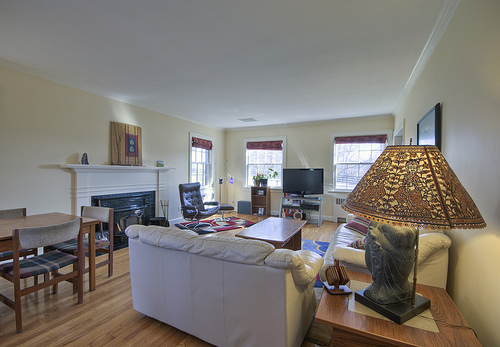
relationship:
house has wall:
[1, 1, 498, 341] [7, 84, 227, 207]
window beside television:
[246, 140, 285, 186] [282, 166, 322, 201]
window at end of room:
[245, 162, 286, 189] [9, 12, 494, 337]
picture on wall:
[106, 121, 153, 169] [45, 98, 110, 158]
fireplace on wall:
[56, 149, 193, 254] [0, 57, 465, 210]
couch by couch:
[118, 217, 318, 345] [318, 209, 447, 291]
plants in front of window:
[249, 166, 280, 186] [243, 139, 287, 190]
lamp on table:
[307, 160, 457, 335] [294, 263, 418, 340]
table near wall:
[294, 263, 418, 340] [395, 0, 497, 343]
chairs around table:
[31, 213, 143, 303] [15, 206, 102, 247]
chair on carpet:
[175, 180, 224, 220] [193, 202, 270, 243]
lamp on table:
[339, 144, 489, 326] [305, 259, 488, 345]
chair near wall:
[178, 182, 221, 232] [6, 75, 221, 270]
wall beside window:
[6, 75, 221, 270] [190, 133, 214, 208]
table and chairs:
[0, 211, 73, 250] [0, 216, 87, 333]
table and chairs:
[0, 211, 73, 250] [77, 204, 116, 282]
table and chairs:
[0, 211, 73, 250] [176, 180, 220, 228]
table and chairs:
[0, 211, 73, 250] [0, 206, 27, 219]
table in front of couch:
[0, 211, 99, 293] [127, 228, 308, 345]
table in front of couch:
[246, 211, 297, 243] [127, 228, 308, 345]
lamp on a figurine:
[339, 144, 489, 326] [355, 219, 420, 303]